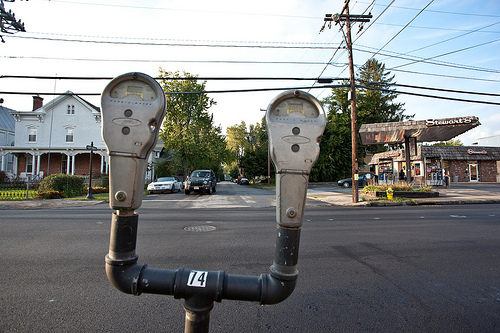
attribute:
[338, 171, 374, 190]
car — parked, black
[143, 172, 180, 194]
car — white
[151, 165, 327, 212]
road — tarmacked, rough, grey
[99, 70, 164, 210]
parking meter — silver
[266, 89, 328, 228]
parking meter — silver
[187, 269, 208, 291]
74 — sticker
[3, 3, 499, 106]
wires — overhead, electric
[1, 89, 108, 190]
house — white, two floors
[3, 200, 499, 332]
street — paved, black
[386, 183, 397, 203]
hydrant — yellow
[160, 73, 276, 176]
trees — green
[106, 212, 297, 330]
pipe — black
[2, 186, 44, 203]
grass — green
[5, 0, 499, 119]
sky — blue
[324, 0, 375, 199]
utility pole — wooden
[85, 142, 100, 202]
street sign — metal